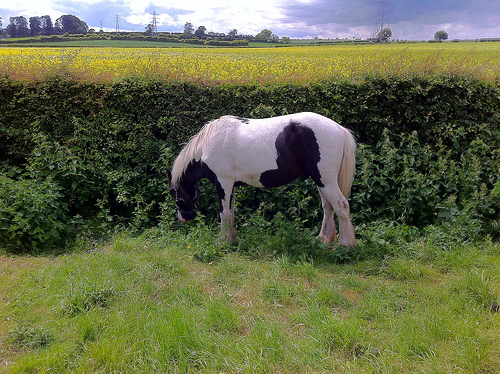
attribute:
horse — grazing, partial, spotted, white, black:
[166, 111, 359, 258]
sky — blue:
[2, 3, 500, 38]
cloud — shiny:
[126, 3, 307, 36]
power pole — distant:
[150, 10, 158, 32]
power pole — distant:
[115, 12, 121, 31]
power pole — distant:
[99, 15, 104, 31]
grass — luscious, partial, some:
[0, 221, 499, 373]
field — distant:
[2, 41, 499, 85]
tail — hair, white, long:
[339, 128, 358, 201]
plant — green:
[95, 197, 115, 233]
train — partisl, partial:
[479, 38, 499, 41]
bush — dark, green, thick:
[1, 73, 499, 157]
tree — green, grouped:
[55, 14, 89, 34]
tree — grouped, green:
[194, 24, 209, 40]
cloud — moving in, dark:
[278, 1, 497, 36]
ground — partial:
[6, 37, 201, 49]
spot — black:
[262, 121, 329, 190]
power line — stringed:
[116, 11, 152, 18]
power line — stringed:
[82, 22, 102, 28]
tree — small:
[434, 30, 448, 42]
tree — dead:
[146, 21, 157, 35]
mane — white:
[172, 117, 219, 185]